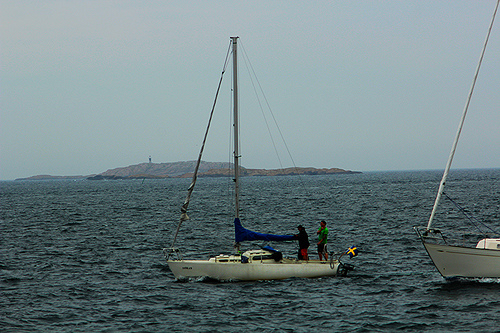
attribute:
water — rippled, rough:
[4, 176, 495, 326]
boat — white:
[166, 255, 344, 282]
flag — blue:
[229, 215, 293, 247]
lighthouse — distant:
[143, 153, 157, 168]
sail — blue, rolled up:
[234, 217, 299, 242]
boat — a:
[65, 102, 382, 331]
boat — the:
[78, 120, 296, 287]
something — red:
[292, 241, 312, 264]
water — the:
[0, 163, 499, 330]